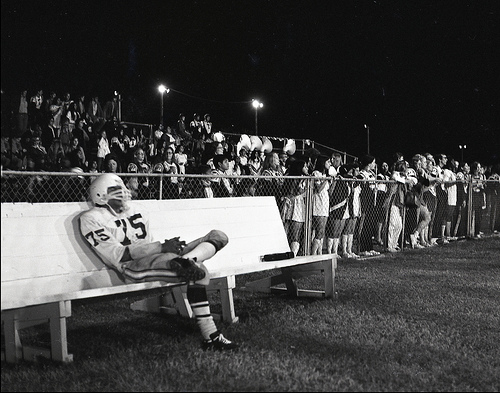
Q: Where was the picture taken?
A: It was taken at the field.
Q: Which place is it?
A: It is a field.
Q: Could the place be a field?
A: Yes, it is a field.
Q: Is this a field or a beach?
A: It is a field.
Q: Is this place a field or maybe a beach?
A: It is a field.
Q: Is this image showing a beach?
A: No, the picture is showing a field.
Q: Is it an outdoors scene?
A: Yes, it is outdoors.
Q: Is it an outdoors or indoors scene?
A: It is outdoors.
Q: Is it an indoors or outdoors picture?
A: It is outdoors.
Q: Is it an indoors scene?
A: No, it is outdoors.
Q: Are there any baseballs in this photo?
A: No, there are no baseballs.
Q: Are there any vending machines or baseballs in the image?
A: No, there are no baseballs or vending machines.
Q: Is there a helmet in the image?
A: Yes, there is a helmet.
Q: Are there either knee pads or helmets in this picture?
A: Yes, there is a helmet.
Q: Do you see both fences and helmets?
A: Yes, there are both a helmet and a fence.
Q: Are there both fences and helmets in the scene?
A: Yes, there are both a helmet and a fence.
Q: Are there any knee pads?
A: No, there are no knee pads.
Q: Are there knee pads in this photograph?
A: No, there are no knee pads.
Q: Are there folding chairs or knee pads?
A: No, there are no knee pads or folding chairs.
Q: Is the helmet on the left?
A: Yes, the helmet is on the left of the image.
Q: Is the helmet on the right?
A: No, the helmet is on the left of the image.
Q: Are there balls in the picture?
A: No, there are no balls.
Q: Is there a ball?
A: No, there are no balls.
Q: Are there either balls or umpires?
A: No, there are no balls or umpires.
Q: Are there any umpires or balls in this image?
A: No, there are no balls or umpires.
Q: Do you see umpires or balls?
A: No, there are no balls or umpires.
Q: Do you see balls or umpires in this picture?
A: No, there are no balls or umpires.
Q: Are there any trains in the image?
A: No, there are no trains.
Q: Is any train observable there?
A: No, there are no trains.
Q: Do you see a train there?
A: No, there are no trains.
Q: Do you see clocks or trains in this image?
A: No, there are no trains or clocks.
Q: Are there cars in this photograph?
A: No, there are no cars.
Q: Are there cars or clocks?
A: No, there are no cars or clocks.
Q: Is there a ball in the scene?
A: No, there are no balls.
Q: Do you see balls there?
A: No, there are no balls.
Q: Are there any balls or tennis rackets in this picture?
A: No, there are no balls or tennis rackets.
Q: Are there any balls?
A: No, there are no balls.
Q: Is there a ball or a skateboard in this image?
A: No, there are no balls or skateboards.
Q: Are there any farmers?
A: No, there are no farmers.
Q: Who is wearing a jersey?
A: The player is wearing a jersey.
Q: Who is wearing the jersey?
A: The player is wearing a jersey.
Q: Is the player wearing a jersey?
A: Yes, the player is wearing a jersey.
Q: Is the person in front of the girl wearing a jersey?
A: Yes, the player is wearing a jersey.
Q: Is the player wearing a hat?
A: No, the player is wearing a jersey.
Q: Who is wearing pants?
A: The player is wearing pants.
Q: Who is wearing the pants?
A: The player is wearing pants.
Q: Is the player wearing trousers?
A: Yes, the player is wearing trousers.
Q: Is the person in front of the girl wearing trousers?
A: Yes, the player is wearing trousers.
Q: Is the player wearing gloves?
A: No, the player is wearing trousers.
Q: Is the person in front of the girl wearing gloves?
A: No, the player is wearing trousers.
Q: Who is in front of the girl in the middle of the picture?
A: The player is in front of the girl.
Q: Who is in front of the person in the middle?
A: The player is in front of the girl.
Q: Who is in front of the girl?
A: The player is in front of the girl.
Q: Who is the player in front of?
A: The player is in front of the girl.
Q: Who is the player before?
A: The player is in front of the girl.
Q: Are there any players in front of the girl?
A: Yes, there is a player in front of the girl.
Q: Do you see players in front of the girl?
A: Yes, there is a player in front of the girl.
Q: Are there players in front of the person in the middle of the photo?
A: Yes, there is a player in front of the girl.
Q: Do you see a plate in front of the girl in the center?
A: No, there is a player in front of the girl.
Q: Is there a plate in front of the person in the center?
A: No, there is a player in front of the girl.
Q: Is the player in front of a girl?
A: Yes, the player is in front of a girl.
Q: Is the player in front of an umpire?
A: No, the player is in front of a girl.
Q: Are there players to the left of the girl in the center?
A: Yes, there is a player to the left of the girl.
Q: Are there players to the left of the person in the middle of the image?
A: Yes, there is a player to the left of the girl.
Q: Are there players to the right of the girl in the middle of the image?
A: No, the player is to the left of the girl.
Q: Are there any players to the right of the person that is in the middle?
A: No, the player is to the left of the girl.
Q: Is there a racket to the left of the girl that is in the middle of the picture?
A: No, there is a player to the left of the girl.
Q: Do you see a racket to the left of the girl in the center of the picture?
A: No, there is a player to the left of the girl.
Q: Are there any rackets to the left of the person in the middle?
A: No, there is a player to the left of the girl.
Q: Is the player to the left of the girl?
A: Yes, the player is to the left of the girl.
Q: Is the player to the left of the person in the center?
A: Yes, the player is to the left of the girl.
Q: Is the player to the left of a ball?
A: No, the player is to the left of the girl.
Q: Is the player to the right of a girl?
A: No, the player is to the left of a girl.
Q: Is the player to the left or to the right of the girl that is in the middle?
A: The player is to the left of the girl.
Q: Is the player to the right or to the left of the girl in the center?
A: The player is to the left of the girl.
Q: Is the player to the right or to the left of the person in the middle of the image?
A: The player is to the left of the girl.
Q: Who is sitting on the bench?
A: The player is sitting on the bench.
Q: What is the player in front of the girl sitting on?
A: The player is sitting on the bench.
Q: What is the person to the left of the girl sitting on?
A: The player is sitting on the bench.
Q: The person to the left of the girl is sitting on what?
A: The player is sitting on the bench.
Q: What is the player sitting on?
A: The player is sitting on the bench.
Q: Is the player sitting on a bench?
A: Yes, the player is sitting on a bench.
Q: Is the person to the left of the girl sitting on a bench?
A: Yes, the player is sitting on a bench.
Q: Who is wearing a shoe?
A: The player is wearing a shoe.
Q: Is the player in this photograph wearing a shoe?
A: Yes, the player is wearing a shoe.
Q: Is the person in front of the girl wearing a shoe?
A: Yes, the player is wearing a shoe.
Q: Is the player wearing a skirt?
A: No, the player is wearing a shoe.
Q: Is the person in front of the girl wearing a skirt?
A: No, the player is wearing a shoe.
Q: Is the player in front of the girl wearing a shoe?
A: Yes, the player is wearing a shoe.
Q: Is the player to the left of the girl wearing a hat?
A: No, the player is wearing a shoe.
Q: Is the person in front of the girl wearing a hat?
A: No, the player is wearing a shoe.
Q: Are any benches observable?
A: Yes, there is a bench.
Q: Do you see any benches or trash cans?
A: Yes, there is a bench.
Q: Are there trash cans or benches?
A: Yes, there is a bench.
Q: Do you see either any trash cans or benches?
A: Yes, there is a bench.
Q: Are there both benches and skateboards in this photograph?
A: No, there is a bench but no skateboards.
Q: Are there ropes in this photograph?
A: No, there are no ropes.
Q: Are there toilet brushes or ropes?
A: No, there are no ropes or toilet brushes.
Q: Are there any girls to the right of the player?
A: Yes, there is a girl to the right of the player.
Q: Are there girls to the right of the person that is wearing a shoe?
A: Yes, there is a girl to the right of the player.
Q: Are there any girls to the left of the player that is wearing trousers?
A: No, the girl is to the right of the player.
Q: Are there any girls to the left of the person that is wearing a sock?
A: No, the girl is to the right of the player.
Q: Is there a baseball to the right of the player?
A: No, there is a girl to the right of the player.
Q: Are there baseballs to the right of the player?
A: No, there is a girl to the right of the player.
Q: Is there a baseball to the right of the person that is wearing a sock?
A: No, there is a girl to the right of the player.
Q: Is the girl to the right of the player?
A: Yes, the girl is to the right of the player.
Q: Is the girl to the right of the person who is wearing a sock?
A: Yes, the girl is to the right of the player.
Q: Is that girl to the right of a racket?
A: No, the girl is to the right of the player.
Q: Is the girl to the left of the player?
A: No, the girl is to the right of the player.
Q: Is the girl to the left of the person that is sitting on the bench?
A: No, the girl is to the right of the player.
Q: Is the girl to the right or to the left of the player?
A: The girl is to the right of the player.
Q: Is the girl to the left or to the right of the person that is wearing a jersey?
A: The girl is to the right of the player.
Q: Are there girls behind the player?
A: Yes, there is a girl behind the player.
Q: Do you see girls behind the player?
A: Yes, there is a girl behind the player.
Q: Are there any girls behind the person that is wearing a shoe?
A: Yes, there is a girl behind the player.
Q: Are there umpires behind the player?
A: No, there is a girl behind the player.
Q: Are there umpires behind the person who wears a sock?
A: No, there is a girl behind the player.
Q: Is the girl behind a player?
A: Yes, the girl is behind a player.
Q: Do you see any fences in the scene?
A: Yes, there is a fence.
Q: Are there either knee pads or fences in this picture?
A: Yes, there is a fence.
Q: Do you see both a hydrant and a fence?
A: No, there is a fence but no fire hydrants.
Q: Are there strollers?
A: No, there are no strollers.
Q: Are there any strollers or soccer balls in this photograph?
A: No, there are no strollers or soccer balls.